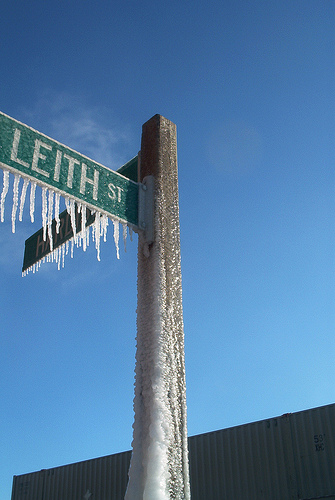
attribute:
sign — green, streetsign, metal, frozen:
[2, 111, 138, 225]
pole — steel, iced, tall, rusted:
[138, 114, 194, 499]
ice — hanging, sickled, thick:
[3, 168, 135, 246]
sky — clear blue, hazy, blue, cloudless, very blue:
[2, 2, 333, 410]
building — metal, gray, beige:
[13, 403, 335, 499]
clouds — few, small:
[54, 114, 125, 169]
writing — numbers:
[310, 430, 328, 455]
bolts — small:
[140, 182, 148, 194]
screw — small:
[142, 221, 148, 229]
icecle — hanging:
[94, 212, 101, 255]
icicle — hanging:
[12, 175, 17, 230]